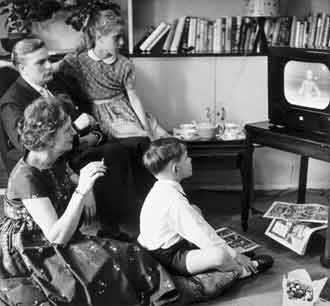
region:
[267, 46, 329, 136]
old TV with a black console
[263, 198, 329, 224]
newspaper on the TV stand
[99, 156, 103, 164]
short cigarette the woman is holding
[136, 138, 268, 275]
little boy watching TV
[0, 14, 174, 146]
little girl watching TV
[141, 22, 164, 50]
white book leaning on the bookshelf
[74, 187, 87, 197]
small bracelet on the woman's wrist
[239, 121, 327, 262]
wooden TV stand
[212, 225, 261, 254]
newspaper in the boy's lap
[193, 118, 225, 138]
glass ceramic pitcher on the table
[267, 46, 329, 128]
an old small t.v.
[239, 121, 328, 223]
part of a t.v. stand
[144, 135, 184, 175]
a boy's short cut hair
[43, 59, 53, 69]
the nose of a man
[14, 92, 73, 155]
a woman's short curly hair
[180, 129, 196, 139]
a tea cup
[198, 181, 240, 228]
part of a floor carpet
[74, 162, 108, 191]
the hand of a woman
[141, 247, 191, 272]
part of a boy's shorts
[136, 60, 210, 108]
part of a white painted wall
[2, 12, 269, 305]
four people seated in front of a tv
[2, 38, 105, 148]
man wearing a suit watching tv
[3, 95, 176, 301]
woman wearing a dress watching tv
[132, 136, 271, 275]
kid wering white t-shirt watching tv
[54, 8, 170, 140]
blonde girl wearing dress watching tv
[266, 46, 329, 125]
black old tv on a table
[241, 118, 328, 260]
brown wooden tv table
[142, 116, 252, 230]
wooden coffee table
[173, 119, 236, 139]
white cups of tea on a coffe table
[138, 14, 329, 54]
books on a counter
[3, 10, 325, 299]
a family sitting together watching TV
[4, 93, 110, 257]
a woman holding a cigarette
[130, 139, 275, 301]
a boy sitting on a pillow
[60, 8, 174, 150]
a girl sitting on the arm of a chair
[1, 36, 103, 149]
a man holding a cigarette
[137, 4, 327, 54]
books on a book shelf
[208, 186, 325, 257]
news papers on a shelf and the floor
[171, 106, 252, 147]
a tea pot and tea cups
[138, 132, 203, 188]
a head of a boy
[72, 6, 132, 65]
a head of a girl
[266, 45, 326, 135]
an old television on a table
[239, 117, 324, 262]
table the television is on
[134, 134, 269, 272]
a boy in a white shirt watching television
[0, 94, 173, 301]
a woman on the floor watching television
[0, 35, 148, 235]
man sitting in a chair watching television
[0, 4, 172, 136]
girl sitting on arm of a chair watching television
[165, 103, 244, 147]
tray with a tea set on it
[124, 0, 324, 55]
shelf of books on the wall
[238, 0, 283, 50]
small lamp on the book shelf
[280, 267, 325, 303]
white container on the floor